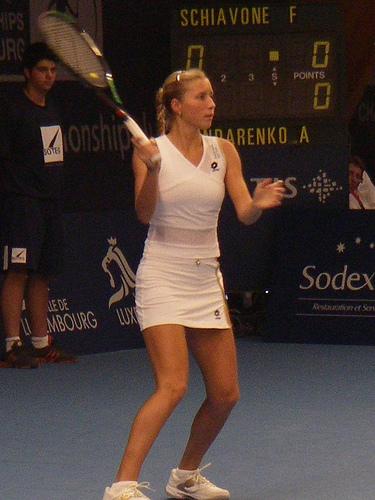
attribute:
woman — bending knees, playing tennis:
[122, 60, 289, 500]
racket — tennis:
[32, 6, 163, 173]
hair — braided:
[154, 63, 208, 136]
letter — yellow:
[296, 124, 310, 145]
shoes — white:
[91, 463, 236, 499]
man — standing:
[3, 38, 79, 378]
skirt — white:
[130, 251, 235, 336]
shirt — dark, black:
[0, 89, 71, 205]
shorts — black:
[0, 193, 62, 277]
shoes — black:
[0, 333, 80, 373]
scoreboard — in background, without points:
[169, 7, 352, 231]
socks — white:
[105, 462, 206, 495]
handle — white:
[124, 113, 161, 167]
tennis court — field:
[0, 321, 369, 499]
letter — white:
[296, 262, 322, 294]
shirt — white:
[139, 129, 227, 261]